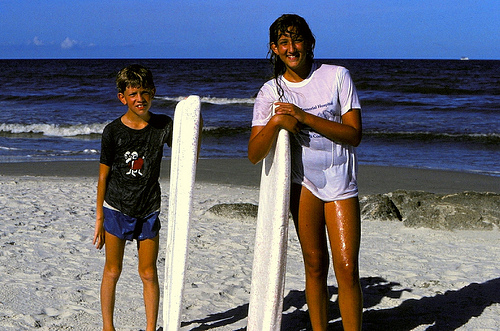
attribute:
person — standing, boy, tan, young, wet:
[92, 63, 203, 330]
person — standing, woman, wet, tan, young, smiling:
[247, 13, 364, 331]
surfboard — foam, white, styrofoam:
[160, 93, 202, 329]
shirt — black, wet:
[98, 112, 173, 218]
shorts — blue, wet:
[103, 207, 162, 241]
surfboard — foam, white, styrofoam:
[246, 102, 291, 330]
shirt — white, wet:
[250, 62, 362, 201]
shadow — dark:
[323, 273, 500, 329]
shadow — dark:
[156, 276, 412, 330]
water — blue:
[0, 57, 500, 175]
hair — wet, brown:
[266, 13, 316, 105]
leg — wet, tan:
[289, 183, 332, 330]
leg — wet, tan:
[324, 196, 365, 330]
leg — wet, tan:
[100, 230, 124, 329]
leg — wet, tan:
[136, 231, 161, 330]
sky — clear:
[0, 0, 499, 59]